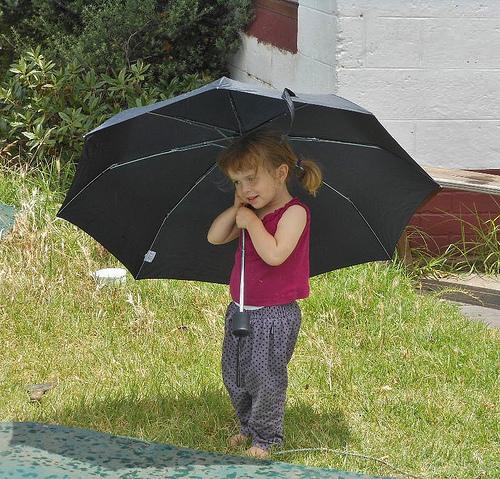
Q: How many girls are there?
A: One.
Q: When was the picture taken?
A: Daytime.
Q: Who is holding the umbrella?
A: The girl.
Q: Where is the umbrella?
A: Over the girl.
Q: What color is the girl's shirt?
A: Purple.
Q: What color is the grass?
A: Green.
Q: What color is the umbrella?
A: Black.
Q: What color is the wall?
A: Red and white.